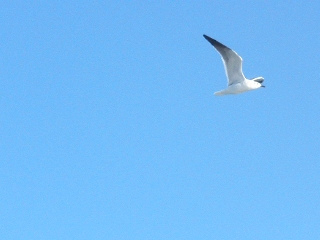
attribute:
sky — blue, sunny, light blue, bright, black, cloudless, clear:
[1, 2, 317, 236]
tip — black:
[202, 34, 233, 52]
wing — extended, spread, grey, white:
[202, 33, 247, 86]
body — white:
[213, 80, 261, 98]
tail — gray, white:
[213, 90, 225, 98]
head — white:
[255, 82, 270, 91]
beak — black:
[260, 84, 267, 88]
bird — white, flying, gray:
[202, 34, 267, 98]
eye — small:
[256, 83, 261, 85]